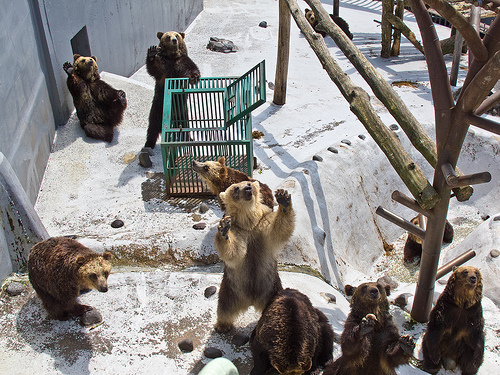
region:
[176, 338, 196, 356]
small stone visible on the ground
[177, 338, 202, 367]
small stone visible on the ground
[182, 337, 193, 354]
small stone visible on the ground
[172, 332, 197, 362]
small stone visible on the ground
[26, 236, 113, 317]
a brown bear sitting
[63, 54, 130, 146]
a brown bear sitting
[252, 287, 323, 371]
a brown bear sitting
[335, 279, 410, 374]
a brown bear sitting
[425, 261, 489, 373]
a brown bear sitting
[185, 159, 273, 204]
a brown bear sitting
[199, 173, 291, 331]
a light brown bear standing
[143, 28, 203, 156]
a brown bear standing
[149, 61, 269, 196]
a large green cage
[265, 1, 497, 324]
a wooden structure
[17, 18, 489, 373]
a hearty handful of many coloured bears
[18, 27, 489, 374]
waving bears @ least as aware of their watchers as their watchers are of them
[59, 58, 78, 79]
the black pads on the dark brown foot of one seated bear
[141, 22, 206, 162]
standing waving bear, trying to lure spectator into large green cage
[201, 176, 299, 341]
largish tannish bear greets spectators, encourages treat-throwing. looks like a raccoon dog but, y'know, isnt.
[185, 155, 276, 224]
juvenile bear in front of green cage, hoping cuteness will encourage treats & spectators' captivity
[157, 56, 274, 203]
large empty cage is green metal, has small square door, looks large enough for bear or person, maybe bear+person [though that might not be good]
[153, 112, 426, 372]
large dark round rocks, mostly black often in an organized line [see rounded ridge]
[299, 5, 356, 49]
bear almost hidden @ back, face visible between two horizontal raw wood poles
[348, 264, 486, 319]
happy faced bear beside dope faced bear, both goofy, lower right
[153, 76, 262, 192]
green open cage visible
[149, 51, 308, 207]
green cage in bear enclosure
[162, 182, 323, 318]
bear standing on two legs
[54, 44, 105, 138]
bear sitting down and waving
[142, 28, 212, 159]
bear standing up and holding cage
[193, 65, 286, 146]
cage door is open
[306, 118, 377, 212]
snow in the enclosure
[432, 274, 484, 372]
bears are brown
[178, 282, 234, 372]
rocks on the ground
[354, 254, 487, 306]
bears are looking up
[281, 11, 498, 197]
trees in the closure for bears to climb